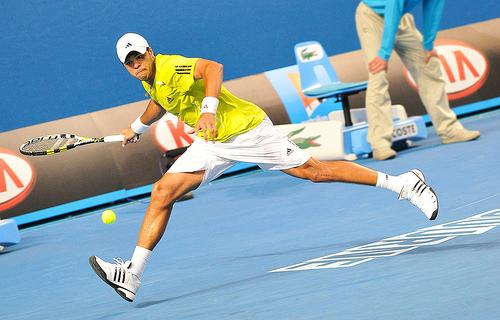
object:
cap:
[113, 32, 150, 64]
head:
[112, 32, 153, 81]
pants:
[352, 2, 462, 150]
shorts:
[159, 114, 314, 191]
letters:
[262, 255, 375, 272]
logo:
[401, 33, 491, 101]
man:
[86, 30, 440, 304]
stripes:
[173, 65, 193, 68]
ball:
[99, 209, 117, 225]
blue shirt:
[360, 0, 447, 63]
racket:
[18, 130, 143, 158]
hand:
[115, 127, 140, 148]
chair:
[291, 39, 371, 130]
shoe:
[395, 168, 442, 223]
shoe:
[86, 252, 142, 302]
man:
[352, 1, 481, 161]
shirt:
[138, 53, 270, 145]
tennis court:
[0, 98, 499, 318]